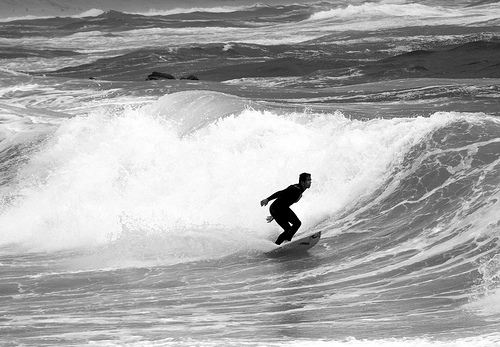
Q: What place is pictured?
A: It is an ocean.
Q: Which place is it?
A: It is an ocean.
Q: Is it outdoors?
A: Yes, it is outdoors.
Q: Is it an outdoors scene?
A: Yes, it is outdoors.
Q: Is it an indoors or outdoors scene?
A: It is outdoors.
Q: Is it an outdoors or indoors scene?
A: It is outdoors.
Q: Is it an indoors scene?
A: No, it is outdoors.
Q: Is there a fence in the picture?
A: No, there are no fences.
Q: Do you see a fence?
A: No, there are no fences.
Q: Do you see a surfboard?
A: Yes, there is a surfboard.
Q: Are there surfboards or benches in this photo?
A: Yes, there is a surfboard.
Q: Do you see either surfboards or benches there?
A: Yes, there is a surfboard.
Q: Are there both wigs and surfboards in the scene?
A: No, there is a surfboard but no wigs.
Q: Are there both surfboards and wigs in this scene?
A: No, there is a surfboard but no wigs.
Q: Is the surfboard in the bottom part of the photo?
A: Yes, the surfboard is in the bottom of the image.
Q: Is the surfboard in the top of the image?
A: No, the surfboard is in the bottom of the image.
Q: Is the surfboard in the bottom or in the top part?
A: The surfboard is in the bottom of the image.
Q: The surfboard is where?
A: The surfboard is in the ocean.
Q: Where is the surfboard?
A: The surfboard is in the ocean.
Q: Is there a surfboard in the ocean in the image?
A: Yes, there is a surfboard in the ocean.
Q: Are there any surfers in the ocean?
A: No, there is a surfboard in the ocean.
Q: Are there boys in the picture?
A: No, there are no boys.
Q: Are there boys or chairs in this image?
A: No, there are no boys or chairs.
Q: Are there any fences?
A: No, there are no fences.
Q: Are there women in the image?
A: No, there are no women.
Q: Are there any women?
A: No, there are no women.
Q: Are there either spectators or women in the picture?
A: No, there are no women or spectators.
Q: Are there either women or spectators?
A: No, there are no women or spectators.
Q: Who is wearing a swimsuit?
A: The guy is wearing a swimsuit.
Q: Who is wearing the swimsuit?
A: The guy is wearing a swimsuit.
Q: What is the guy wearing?
A: The guy is wearing a swimsuit.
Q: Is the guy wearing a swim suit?
A: Yes, the guy is wearing a swim suit.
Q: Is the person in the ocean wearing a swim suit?
A: Yes, the guy is wearing a swim suit.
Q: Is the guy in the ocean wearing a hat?
A: No, the guy is wearing a swim suit.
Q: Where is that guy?
A: The guy is in the ocean.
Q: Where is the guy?
A: The guy is in the ocean.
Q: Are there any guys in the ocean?
A: Yes, there is a guy in the ocean.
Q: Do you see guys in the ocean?
A: Yes, there is a guy in the ocean.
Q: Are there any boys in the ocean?
A: No, there is a guy in the ocean.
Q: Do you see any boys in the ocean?
A: No, there is a guy in the ocean.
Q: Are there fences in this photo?
A: No, there are no fences.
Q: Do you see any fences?
A: No, there are no fences.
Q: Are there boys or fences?
A: No, there are no fences or boys.